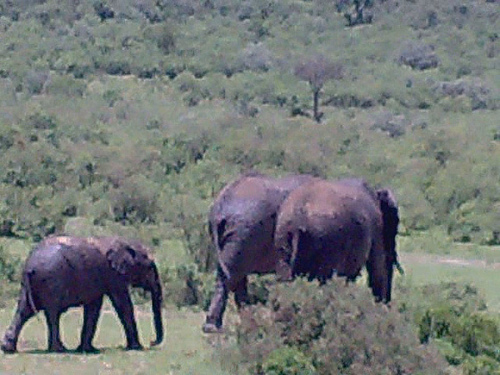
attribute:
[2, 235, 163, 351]
baby elephant — following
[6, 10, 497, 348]
bushes — distant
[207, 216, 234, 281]
tail — long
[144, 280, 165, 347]
trunk — long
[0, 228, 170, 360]
elephant — walking, baby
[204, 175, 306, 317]
elephant — large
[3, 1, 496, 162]
bushes — tall, green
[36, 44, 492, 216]
bushes — tall, green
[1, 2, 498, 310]
bushes — green, tall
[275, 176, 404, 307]
elephant — large, brown, walking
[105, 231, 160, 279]
ear — large, gray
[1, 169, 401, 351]
elephants — togehter, walking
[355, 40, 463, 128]
bushes — tall, green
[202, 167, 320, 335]
elephant — walking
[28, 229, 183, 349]
elephant — baby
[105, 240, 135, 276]
ear — gray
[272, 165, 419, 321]
elephant — large